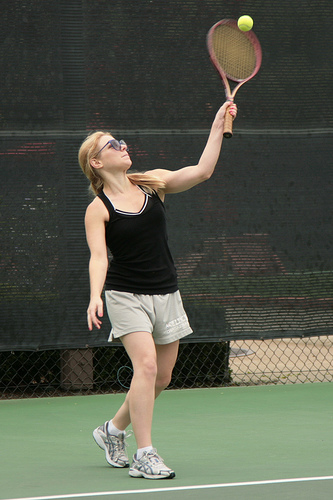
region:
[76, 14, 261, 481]
Girl playing tennis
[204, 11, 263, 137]
Racket hitting the ball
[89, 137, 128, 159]
Sunglasses on girl's face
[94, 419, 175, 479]
Sneakers and socks on girl's feet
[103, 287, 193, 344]
Grey shorts on tennis player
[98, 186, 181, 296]
Black tank top on woman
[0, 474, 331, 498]
White line on the tennis court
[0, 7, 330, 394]
Wire fence behind the girl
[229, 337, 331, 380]
Pavement behind the fence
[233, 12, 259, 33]
Yellow tennis ball in front of racket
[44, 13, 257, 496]
woman playing tennis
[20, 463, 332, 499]
white line on the court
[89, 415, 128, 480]
heel is lifted in the air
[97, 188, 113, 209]
thick black strap of the shirt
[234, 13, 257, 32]
bright yellow tennis ball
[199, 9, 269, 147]
ball about to make contact with the racket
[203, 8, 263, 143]
tennis racket in the air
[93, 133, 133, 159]
glasses on the face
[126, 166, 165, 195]
hair laying over the shoulder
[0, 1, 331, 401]
tall fence on the edge of the court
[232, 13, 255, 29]
yellow tennis ball in air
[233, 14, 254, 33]
green tennis ball in air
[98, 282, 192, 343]
white shorts on woman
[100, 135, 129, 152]
sun glasses on face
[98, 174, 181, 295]
black tank top on woman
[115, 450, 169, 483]
white tennis shoe on foot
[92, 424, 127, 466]
white tennis shoe on foot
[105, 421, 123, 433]
white sock on foot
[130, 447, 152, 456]
white sock on foot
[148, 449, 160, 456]
white shoe lace on shoe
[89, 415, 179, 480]
Woman wearing shoes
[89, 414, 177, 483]
Woman is wearing shoes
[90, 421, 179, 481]
Woman wearing white and gray shoes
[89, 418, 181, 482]
Woman is wearing white and gray shoes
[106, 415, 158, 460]
Woman wearing socks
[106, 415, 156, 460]
Woman is wearing socks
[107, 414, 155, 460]
Woman wearing white socks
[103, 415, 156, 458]
Woman is wearing white socks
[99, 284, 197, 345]
Woman wearing shorts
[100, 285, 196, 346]
Woman is wearing shorts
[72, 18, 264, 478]
a female tennis player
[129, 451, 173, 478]
a black and white tennis shoe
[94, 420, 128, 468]
a black and white tennis shoe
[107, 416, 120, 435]
a small white anklet sock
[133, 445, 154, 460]
a small white anklet sock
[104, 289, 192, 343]
a pair of grey shorts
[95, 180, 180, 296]
a woman's black tennis top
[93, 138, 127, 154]
a pair of sunglasses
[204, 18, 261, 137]
a red tennis racket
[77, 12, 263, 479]
a woman hitting a tennis ball